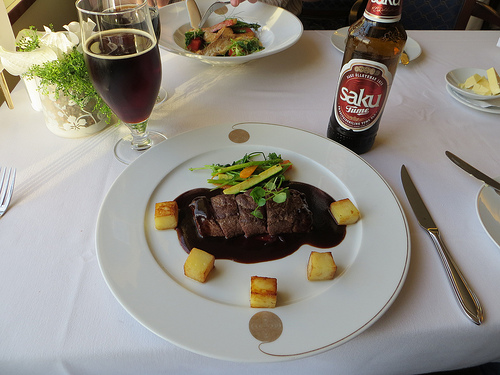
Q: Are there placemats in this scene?
A: No, there are no placemats.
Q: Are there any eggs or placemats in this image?
A: No, there are no placemats or eggs.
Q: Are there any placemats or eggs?
A: No, there are no placemats or eggs.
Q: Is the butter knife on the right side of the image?
A: Yes, the butter knife is on the right of the image.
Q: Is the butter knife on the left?
A: No, the butter knife is on the right of the image.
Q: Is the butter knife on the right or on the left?
A: The butter knife is on the right of the image.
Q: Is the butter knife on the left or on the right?
A: The butter knife is on the right of the image.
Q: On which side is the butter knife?
A: The butter knife is on the right of the image.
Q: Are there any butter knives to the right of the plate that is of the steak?
A: Yes, there is a butter knife to the right of the plate.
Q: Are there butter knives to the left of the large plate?
A: No, the butter knife is to the right of the plate.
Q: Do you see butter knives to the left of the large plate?
A: No, the butter knife is to the right of the plate.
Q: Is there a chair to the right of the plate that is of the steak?
A: No, there is a butter knife to the right of the plate.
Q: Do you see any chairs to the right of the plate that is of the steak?
A: No, there is a butter knife to the right of the plate.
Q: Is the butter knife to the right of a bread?
A: No, the butter knife is to the right of the plate.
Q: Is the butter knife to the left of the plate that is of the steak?
A: No, the butter knife is to the right of the plate.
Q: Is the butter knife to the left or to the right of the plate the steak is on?
A: The butter knife is to the right of the plate.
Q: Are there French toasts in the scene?
A: No, there are no French toasts.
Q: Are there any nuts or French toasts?
A: No, there are no French toasts or nuts.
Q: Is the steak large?
A: Yes, the steak is large.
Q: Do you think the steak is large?
A: Yes, the steak is large.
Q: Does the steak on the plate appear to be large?
A: Yes, the steak is large.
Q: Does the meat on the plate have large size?
A: Yes, the steak is large.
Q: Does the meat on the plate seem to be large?
A: Yes, the steak is large.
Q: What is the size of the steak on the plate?
A: The steak is large.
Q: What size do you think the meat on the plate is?
A: The steak is large.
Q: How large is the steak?
A: The steak is large.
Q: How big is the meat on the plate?
A: The steak is large.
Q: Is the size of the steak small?
A: No, the steak is large.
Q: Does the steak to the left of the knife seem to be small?
A: No, the steak is large.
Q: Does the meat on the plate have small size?
A: No, the steak is large.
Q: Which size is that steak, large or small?
A: The steak is large.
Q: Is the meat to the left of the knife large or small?
A: The steak is large.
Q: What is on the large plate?
A: The steak is on the plate.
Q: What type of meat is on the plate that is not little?
A: The meat is a steak.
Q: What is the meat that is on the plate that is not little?
A: The meat is a steak.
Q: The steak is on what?
A: The steak is on the plate.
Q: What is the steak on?
A: The steak is on the plate.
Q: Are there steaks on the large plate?
A: Yes, there is a steak on the plate.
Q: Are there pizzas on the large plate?
A: No, there is a steak on the plate.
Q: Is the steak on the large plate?
A: Yes, the steak is on the plate.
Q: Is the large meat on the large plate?
A: Yes, the steak is on the plate.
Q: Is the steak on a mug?
A: No, the steak is on the plate.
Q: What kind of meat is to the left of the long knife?
A: The meat is a steak.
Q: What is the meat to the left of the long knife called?
A: The meat is a steak.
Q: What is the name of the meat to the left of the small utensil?
A: The meat is a steak.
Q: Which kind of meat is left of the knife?
A: The meat is a steak.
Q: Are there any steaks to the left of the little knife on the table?
A: Yes, there is a steak to the left of the knife.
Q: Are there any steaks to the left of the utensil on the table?
A: Yes, there is a steak to the left of the knife.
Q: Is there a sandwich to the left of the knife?
A: No, there is a steak to the left of the knife.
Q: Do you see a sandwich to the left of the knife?
A: No, there is a steak to the left of the knife.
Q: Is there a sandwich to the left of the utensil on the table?
A: No, there is a steak to the left of the knife.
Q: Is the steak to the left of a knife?
A: Yes, the steak is to the left of a knife.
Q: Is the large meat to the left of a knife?
A: Yes, the steak is to the left of a knife.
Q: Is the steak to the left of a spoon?
A: No, the steak is to the left of a knife.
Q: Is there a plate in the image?
A: Yes, there is a plate.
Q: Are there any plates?
A: Yes, there is a plate.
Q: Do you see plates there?
A: Yes, there is a plate.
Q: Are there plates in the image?
A: Yes, there is a plate.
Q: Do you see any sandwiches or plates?
A: Yes, there is a plate.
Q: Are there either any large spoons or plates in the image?
A: Yes, there is a large plate.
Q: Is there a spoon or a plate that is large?
A: Yes, the plate is large.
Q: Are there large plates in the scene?
A: Yes, there is a large plate.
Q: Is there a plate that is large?
A: Yes, there is a plate that is large.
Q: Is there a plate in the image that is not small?
A: Yes, there is a large plate.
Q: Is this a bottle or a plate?
A: This is a plate.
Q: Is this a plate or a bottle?
A: This is a plate.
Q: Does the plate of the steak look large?
A: Yes, the plate is large.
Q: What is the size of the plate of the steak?
A: The plate is large.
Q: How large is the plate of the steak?
A: The plate is large.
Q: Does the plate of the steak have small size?
A: No, the plate is large.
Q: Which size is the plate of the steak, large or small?
A: The plate is large.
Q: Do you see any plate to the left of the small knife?
A: Yes, there is a plate to the left of the knife.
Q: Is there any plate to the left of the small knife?
A: Yes, there is a plate to the left of the knife.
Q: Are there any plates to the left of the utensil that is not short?
A: Yes, there is a plate to the left of the knife.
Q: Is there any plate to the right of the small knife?
A: No, the plate is to the left of the knife.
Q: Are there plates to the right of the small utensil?
A: No, the plate is to the left of the knife.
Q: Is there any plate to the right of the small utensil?
A: No, the plate is to the left of the knife.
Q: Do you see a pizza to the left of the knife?
A: No, there is a plate to the left of the knife.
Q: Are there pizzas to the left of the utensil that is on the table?
A: No, there is a plate to the left of the knife.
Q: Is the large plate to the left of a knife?
A: Yes, the plate is to the left of a knife.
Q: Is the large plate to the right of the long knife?
A: No, the plate is to the left of the knife.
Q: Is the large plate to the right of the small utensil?
A: No, the plate is to the left of the knife.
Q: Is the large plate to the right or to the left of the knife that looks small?
A: The plate is to the left of the knife.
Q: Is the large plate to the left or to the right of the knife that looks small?
A: The plate is to the left of the knife.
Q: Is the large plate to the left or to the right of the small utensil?
A: The plate is to the left of the knife.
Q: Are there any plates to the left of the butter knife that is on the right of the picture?
A: Yes, there is a plate to the left of the butter knife.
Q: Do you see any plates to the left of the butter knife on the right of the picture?
A: Yes, there is a plate to the left of the butter knife.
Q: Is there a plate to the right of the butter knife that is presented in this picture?
A: No, the plate is to the left of the butter knife.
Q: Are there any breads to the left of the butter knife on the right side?
A: No, there is a plate to the left of the butter knife.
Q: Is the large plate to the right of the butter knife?
A: No, the plate is to the left of the butter knife.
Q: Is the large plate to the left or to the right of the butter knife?
A: The plate is to the left of the butter knife.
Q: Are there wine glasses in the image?
A: Yes, there is a wine glass.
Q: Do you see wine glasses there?
A: Yes, there is a wine glass.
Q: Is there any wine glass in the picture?
A: Yes, there is a wine glass.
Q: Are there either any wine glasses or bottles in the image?
A: Yes, there is a wine glass.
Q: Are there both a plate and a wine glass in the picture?
A: Yes, there are both a wine glass and a plate.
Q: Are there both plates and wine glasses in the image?
A: Yes, there are both a wine glass and a plate.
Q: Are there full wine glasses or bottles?
A: Yes, there is a full wine glass.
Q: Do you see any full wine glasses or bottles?
A: Yes, there is a full wine glass.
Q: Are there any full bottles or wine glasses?
A: Yes, there is a full wine glass.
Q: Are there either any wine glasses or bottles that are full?
A: Yes, the wine glass is full.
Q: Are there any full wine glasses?
A: Yes, there is a full wine glass.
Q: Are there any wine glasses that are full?
A: Yes, there is a wine glass that is full.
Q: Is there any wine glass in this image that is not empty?
A: Yes, there is an full wine glass.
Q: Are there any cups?
A: No, there are no cups.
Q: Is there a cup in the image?
A: No, there are no cups.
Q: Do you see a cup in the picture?
A: No, there are no cups.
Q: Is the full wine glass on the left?
A: Yes, the wineglass is on the left of the image.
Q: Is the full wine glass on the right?
A: No, the wineglass is on the left of the image.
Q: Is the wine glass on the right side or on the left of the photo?
A: The wine glass is on the left of the image.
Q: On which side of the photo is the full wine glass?
A: The wineglass is on the left of the image.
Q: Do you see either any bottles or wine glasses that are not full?
A: No, there is a wine glass but it is full.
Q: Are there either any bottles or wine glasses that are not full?
A: No, there is a wine glass but it is full.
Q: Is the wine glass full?
A: Yes, the wine glass is full.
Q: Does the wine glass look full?
A: Yes, the wine glass is full.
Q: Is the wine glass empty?
A: No, the wine glass is full.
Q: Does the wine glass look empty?
A: No, the wine glass is full.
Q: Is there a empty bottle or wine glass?
A: No, there is a wine glass but it is full.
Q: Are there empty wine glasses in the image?
A: No, there is a wine glass but it is full.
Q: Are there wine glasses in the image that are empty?
A: No, there is a wine glass but it is full.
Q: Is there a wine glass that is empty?
A: No, there is a wine glass but it is full.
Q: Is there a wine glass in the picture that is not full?
A: No, there is a wine glass but it is full.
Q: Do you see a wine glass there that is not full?
A: No, there is a wine glass but it is full.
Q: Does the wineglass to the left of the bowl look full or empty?
A: The wine glass is full.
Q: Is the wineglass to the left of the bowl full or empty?
A: The wine glass is full.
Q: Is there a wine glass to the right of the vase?
A: Yes, there is a wine glass to the right of the vase.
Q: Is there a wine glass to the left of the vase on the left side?
A: No, the wine glass is to the right of the vase.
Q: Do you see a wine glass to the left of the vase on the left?
A: No, the wine glass is to the right of the vase.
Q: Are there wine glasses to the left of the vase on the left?
A: No, the wine glass is to the right of the vase.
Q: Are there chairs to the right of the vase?
A: No, there is a wine glass to the right of the vase.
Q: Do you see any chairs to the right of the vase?
A: No, there is a wine glass to the right of the vase.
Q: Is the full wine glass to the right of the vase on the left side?
A: Yes, the wineglass is to the right of the vase.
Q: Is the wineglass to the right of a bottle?
A: No, the wineglass is to the right of the vase.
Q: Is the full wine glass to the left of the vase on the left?
A: No, the wineglass is to the right of the vase.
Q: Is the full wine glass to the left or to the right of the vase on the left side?
A: The wineglass is to the right of the vase.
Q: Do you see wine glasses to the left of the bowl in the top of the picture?
A: Yes, there is a wine glass to the left of the bowl.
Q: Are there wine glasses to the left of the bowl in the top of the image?
A: Yes, there is a wine glass to the left of the bowl.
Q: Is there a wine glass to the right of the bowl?
A: No, the wine glass is to the left of the bowl.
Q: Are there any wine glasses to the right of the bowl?
A: No, the wine glass is to the left of the bowl.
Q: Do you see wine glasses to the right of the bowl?
A: No, the wine glass is to the left of the bowl.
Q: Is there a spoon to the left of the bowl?
A: No, there is a wine glass to the left of the bowl.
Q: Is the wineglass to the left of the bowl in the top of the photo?
A: Yes, the wineglass is to the left of the bowl.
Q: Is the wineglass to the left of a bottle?
A: No, the wineglass is to the left of the bowl.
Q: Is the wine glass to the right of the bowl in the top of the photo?
A: No, the wine glass is to the left of the bowl.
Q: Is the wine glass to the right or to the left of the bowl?
A: The wine glass is to the left of the bowl.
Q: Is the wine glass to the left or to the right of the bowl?
A: The wine glass is to the left of the bowl.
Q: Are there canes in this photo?
A: No, there are no canes.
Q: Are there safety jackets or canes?
A: No, there are no canes or safety jackets.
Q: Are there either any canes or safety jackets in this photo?
A: No, there are no canes or safety jackets.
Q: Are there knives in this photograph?
A: Yes, there is a knife.